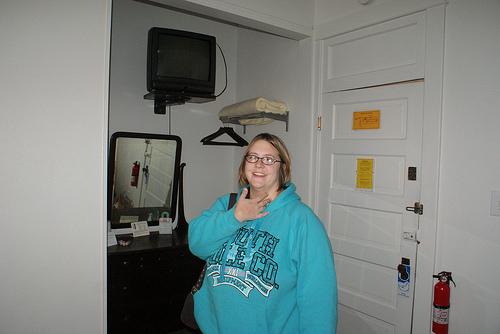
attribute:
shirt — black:
[165, 112, 372, 332]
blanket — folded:
[210, 87, 292, 126]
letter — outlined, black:
[264, 257, 279, 282]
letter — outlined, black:
[252, 252, 263, 277]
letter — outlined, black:
[235, 246, 245, 268]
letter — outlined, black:
[223, 243, 231, 263]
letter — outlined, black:
[208, 246, 218, 261]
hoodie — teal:
[187, 178, 339, 330]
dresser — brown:
[110, 234, 194, 304]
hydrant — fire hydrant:
[421, 245, 459, 332]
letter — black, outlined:
[230, 245, 250, 270]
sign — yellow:
[347, 156, 383, 197]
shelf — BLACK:
[143, 86, 221, 113]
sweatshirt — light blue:
[183, 181, 340, 332]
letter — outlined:
[231, 224, 254, 244]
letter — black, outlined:
[261, 257, 281, 290]